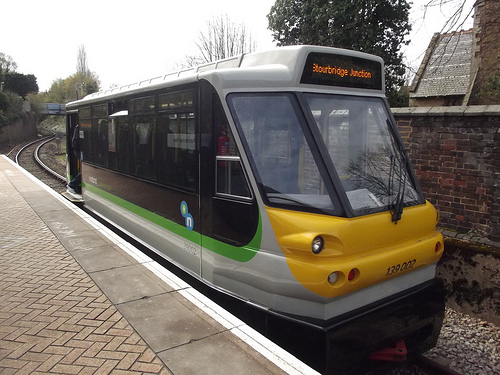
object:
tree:
[265, 0, 412, 106]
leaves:
[299, 10, 309, 18]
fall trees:
[41, 46, 100, 110]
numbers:
[409, 259, 416, 269]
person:
[67, 120, 84, 195]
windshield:
[299, 91, 423, 218]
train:
[60, 44, 447, 375]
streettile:
[112, 291, 221, 354]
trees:
[1, 72, 39, 102]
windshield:
[224, 92, 347, 219]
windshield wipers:
[384, 119, 409, 226]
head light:
[311, 235, 325, 255]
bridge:
[34, 103, 67, 115]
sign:
[179, 200, 194, 231]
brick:
[127, 360, 165, 375]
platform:
[0, 152, 324, 374]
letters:
[186, 217, 192, 228]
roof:
[408, 28, 472, 98]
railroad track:
[13, 127, 69, 199]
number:
[385, 267, 391, 277]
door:
[65, 111, 82, 201]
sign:
[312, 63, 372, 80]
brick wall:
[297, 104, 500, 251]